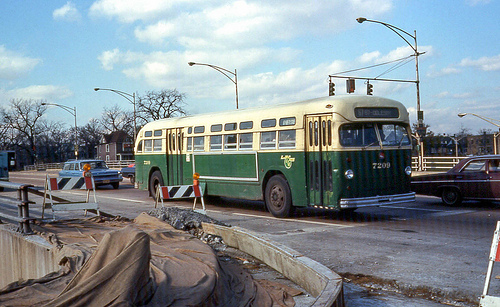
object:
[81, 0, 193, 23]
clouds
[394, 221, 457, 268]
road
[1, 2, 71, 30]
sky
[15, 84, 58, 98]
clouds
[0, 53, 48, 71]
clouds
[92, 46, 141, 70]
clouds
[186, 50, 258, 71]
clouds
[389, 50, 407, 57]
clouds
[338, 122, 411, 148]
windshield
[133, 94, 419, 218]
bus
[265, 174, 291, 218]
tire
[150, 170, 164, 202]
tire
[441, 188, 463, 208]
tire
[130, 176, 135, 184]
tire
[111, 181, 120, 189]
tire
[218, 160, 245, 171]
green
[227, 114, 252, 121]
white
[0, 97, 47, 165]
tree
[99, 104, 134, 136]
tree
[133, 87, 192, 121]
tree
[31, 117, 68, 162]
tree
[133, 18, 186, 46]
clouds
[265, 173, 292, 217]
wheel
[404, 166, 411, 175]
headlight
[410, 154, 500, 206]
car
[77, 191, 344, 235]
roadwork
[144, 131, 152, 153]
window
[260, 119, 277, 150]
window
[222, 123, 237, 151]
window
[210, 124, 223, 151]
window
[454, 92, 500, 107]
sky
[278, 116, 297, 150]
window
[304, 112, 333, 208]
doors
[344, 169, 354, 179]
head light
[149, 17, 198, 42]
sky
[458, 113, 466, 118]
street light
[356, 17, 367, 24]
street light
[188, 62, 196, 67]
street light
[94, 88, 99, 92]
street light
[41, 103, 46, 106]
street light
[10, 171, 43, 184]
road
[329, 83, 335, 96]
traffic lights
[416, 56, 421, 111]
pole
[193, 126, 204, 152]
window